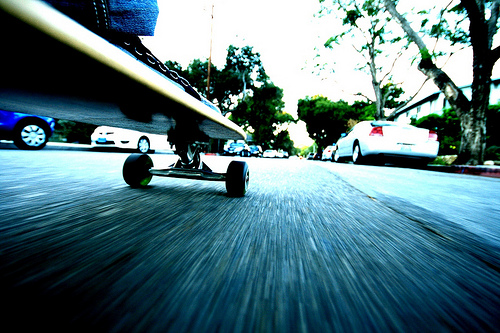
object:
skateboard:
[0, 1, 248, 141]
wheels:
[123, 154, 251, 198]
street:
[0, 149, 499, 332]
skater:
[46, 0, 222, 113]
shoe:
[93, 29, 223, 116]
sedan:
[332, 119, 440, 166]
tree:
[380, 0, 500, 166]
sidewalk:
[428, 160, 500, 179]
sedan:
[89, 125, 172, 155]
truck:
[147, 131, 225, 184]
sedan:
[222, 140, 250, 157]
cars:
[225, 139, 291, 158]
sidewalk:
[200, 151, 226, 159]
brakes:
[369, 124, 440, 142]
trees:
[227, 85, 412, 159]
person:
[44, 1, 217, 114]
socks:
[100, 34, 202, 101]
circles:
[123, 38, 194, 93]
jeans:
[39, 0, 159, 37]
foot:
[45, 22, 200, 104]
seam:
[91, 0, 114, 29]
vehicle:
[0, 104, 56, 151]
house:
[391, 79, 498, 125]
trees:
[297, 1, 499, 165]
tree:
[229, 81, 296, 155]